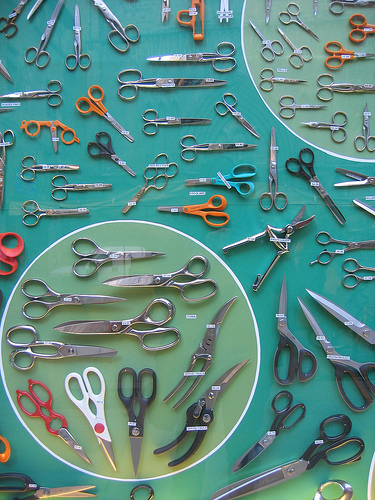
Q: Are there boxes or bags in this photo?
A: No, there are no boxes or bags.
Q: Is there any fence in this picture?
A: No, there are no fences.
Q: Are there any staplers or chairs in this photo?
A: No, there are no chairs or staplers.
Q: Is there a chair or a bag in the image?
A: No, there are no chairs or bags.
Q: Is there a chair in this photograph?
A: No, there are no chairs.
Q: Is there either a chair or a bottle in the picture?
A: No, there are no chairs or bottles.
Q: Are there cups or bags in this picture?
A: No, there are no cups or bags.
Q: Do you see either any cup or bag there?
A: No, there are no cups or bags.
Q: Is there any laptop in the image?
A: No, there are no laptops.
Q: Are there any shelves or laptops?
A: No, there are no laptops or shelves.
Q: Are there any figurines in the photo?
A: No, there are no figurines.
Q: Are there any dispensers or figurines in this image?
A: No, there are no figurines or dispensers.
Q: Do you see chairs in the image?
A: No, there are no chairs.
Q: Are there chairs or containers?
A: No, there are no chairs or containers.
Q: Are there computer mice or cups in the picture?
A: No, there are no cups or computer mice.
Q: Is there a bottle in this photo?
A: No, there are no bottles.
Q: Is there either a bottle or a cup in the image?
A: No, there are no bottles or cups.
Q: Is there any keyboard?
A: No, there are no keyboards.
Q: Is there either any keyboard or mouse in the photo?
A: No, there are no keyboards or computer mice.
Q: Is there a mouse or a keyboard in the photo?
A: No, there are no keyboards or computer mice.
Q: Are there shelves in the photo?
A: No, there are no shelves.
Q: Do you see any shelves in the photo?
A: No, there are no shelves.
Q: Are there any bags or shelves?
A: No, there are no shelves or bags.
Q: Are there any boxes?
A: No, there are no boxes.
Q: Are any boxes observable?
A: No, there are no boxes.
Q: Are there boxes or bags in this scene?
A: No, there are no boxes or bags.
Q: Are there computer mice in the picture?
A: No, there are no computer mice.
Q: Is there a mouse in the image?
A: No, there are no computer mice.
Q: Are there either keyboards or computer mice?
A: No, there are no computer mice or keyboards.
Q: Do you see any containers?
A: No, there are no containers.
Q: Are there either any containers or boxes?
A: No, there are no containers or boxes.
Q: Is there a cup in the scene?
A: No, there are no cups.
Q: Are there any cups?
A: No, there are no cups.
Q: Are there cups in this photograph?
A: No, there are no cups.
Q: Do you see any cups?
A: No, there are no cups.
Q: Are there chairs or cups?
A: No, there are no cups or chairs.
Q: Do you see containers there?
A: No, there are no containers.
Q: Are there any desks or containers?
A: No, there are no containers or desks.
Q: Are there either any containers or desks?
A: No, there are no containers or desks.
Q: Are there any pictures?
A: No, there are no pictures.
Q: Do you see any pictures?
A: No, there are no pictures.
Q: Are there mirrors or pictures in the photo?
A: No, there are no pictures or mirrors.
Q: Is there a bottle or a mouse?
A: No, there are no bottles or computer mice.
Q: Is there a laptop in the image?
A: No, there are no laptops.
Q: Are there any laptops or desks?
A: No, there are no laptops or desks.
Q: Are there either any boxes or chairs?
A: No, there are no boxes or chairs.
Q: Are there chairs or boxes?
A: No, there are no boxes or chairs.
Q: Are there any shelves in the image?
A: No, there are no shelves.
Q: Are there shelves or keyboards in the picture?
A: No, there are no shelves or keyboards.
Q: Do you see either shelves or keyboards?
A: No, there are no shelves or keyboards.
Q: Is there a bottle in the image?
A: No, there are no bottles.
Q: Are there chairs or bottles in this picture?
A: No, there are no bottles or chairs.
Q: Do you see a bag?
A: No, there are no bags.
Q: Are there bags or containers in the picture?
A: No, there are no bags or containers.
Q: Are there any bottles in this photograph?
A: No, there are no bottles.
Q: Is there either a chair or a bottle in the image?
A: No, there are no bottles or chairs.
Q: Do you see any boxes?
A: No, there are no boxes.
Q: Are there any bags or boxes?
A: No, there are no boxes or bags.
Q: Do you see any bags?
A: No, there are no bags.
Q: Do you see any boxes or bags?
A: No, there are no boxes or bags.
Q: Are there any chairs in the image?
A: No, there are no chairs.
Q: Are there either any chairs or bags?
A: No, there are no chairs or bags.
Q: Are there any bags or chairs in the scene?
A: No, there are no chairs or bags.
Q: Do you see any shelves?
A: No, there are no shelves.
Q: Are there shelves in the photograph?
A: No, there are no shelves.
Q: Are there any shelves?
A: No, there are no shelves.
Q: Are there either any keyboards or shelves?
A: No, there are no shelves or keyboards.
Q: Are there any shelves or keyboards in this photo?
A: No, there are no shelves or keyboards.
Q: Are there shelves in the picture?
A: No, there are no shelves.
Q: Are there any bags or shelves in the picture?
A: No, there are no shelves or bags.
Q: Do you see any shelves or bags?
A: No, there are no shelves or bags.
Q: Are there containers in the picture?
A: No, there are no containers.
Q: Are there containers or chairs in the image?
A: No, there are no containers or chairs.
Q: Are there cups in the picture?
A: No, there are no cups.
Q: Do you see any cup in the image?
A: No, there are no cups.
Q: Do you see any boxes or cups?
A: No, there are no cups or boxes.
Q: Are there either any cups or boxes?
A: No, there are no cups or boxes.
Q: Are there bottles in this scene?
A: No, there are no bottles.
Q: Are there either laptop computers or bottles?
A: No, there are no bottles or laptop computers.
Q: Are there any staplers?
A: No, there are no staplers.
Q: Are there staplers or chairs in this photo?
A: No, there are no staplers or chairs.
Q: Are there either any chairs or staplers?
A: No, there are no staplers or chairs.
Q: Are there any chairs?
A: No, there are no chairs.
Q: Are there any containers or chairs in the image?
A: No, there are no chairs or containers.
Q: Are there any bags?
A: No, there are no bags.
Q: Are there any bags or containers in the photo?
A: No, there are no bags or containers.